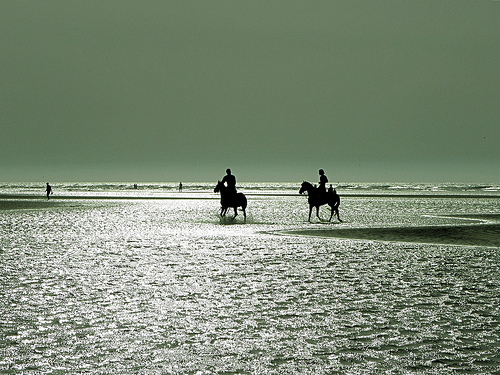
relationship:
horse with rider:
[207, 183, 250, 223] [216, 168, 241, 188]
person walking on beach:
[36, 177, 56, 194] [41, 207, 64, 222]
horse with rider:
[297, 183, 342, 215] [305, 165, 333, 186]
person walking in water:
[36, 177, 56, 194] [32, 203, 61, 221]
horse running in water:
[207, 183, 250, 223] [32, 203, 61, 221]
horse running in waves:
[207, 183, 250, 223] [203, 258, 254, 277]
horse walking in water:
[207, 183, 250, 223] [32, 203, 61, 221]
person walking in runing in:
[36, 177, 56, 194] [209, 230, 245, 243]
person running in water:
[36, 177, 56, 194] [32, 203, 61, 221]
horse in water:
[207, 183, 250, 223] [32, 203, 61, 221]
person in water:
[36, 177, 56, 194] [32, 203, 61, 221]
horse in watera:
[207, 183, 250, 223] [251, 245, 293, 265]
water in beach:
[32, 203, 61, 221] [41, 207, 64, 222]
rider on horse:
[216, 168, 241, 188] [207, 183, 250, 223]